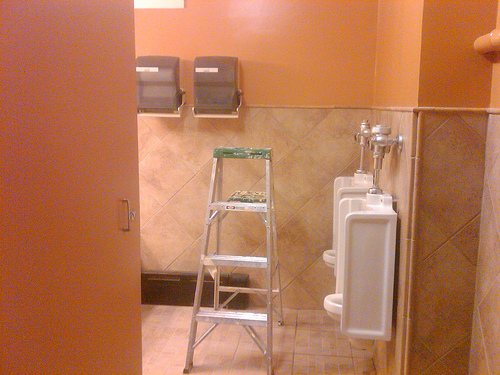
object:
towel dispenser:
[135, 54, 185, 119]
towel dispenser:
[192, 55, 242, 120]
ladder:
[184, 145, 283, 374]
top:
[214, 146, 273, 160]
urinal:
[322, 119, 378, 278]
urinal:
[323, 124, 404, 343]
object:
[141, 269, 250, 310]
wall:
[134, 0, 500, 375]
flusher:
[354, 120, 372, 149]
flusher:
[368, 124, 396, 159]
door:
[0, 0, 144, 374]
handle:
[122, 198, 131, 232]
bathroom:
[0, 0, 499, 374]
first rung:
[195, 309, 268, 328]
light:
[228, 1, 285, 33]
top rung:
[209, 198, 268, 214]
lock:
[129, 210, 136, 221]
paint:
[228, 190, 269, 203]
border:
[182, 105, 499, 114]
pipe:
[472, 28, 500, 54]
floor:
[140, 303, 381, 374]